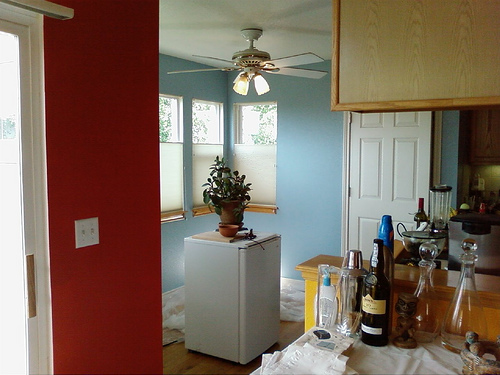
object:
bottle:
[358, 238, 393, 347]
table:
[247, 315, 499, 375]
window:
[190, 97, 226, 209]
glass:
[437, 238, 489, 355]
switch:
[73, 216, 100, 250]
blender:
[426, 183, 451, 233]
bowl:
[400, 230, 448, 261]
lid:
[401, 230, 448, 239]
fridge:
[181, 229, 281, 365]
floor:
[161, 270, 304, 374]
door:
[342, 110, 432, 262]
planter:
[214, 208, 245, 224]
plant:
[200, 156, 253, 225]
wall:
[44, 2, 166, 375]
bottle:
[368, 214, 393, 334]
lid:
[375, 215, 395, 246]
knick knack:
[389, 292, 420, 349]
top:
[417, 197, 425, 210]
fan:
[164, 28, 327, 97]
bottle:
[405, 242, 443, 345]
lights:
[251, 74, 272, 98]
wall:
[158, 53, 342, 296]